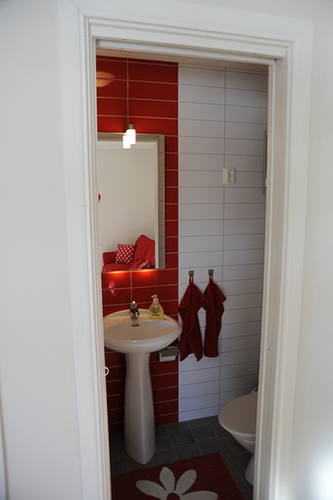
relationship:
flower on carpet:
[135, 465, 218, 500] [111, 448, 249, 500]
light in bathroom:
[121, 123, 137, 154] [93, 46, 264, 496]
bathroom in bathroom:
[0, 0, 333, 499] [93, 46, 264, 496]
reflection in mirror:
[103, 209, 163, 270] [98, 135, 160, 272]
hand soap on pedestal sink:
[148, 295, 164, 322] [103, 305, 183, 465]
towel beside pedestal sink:
[178, 271, 205, 362] [103, 305, 183, 465]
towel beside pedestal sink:
[203, 268, 225, 356] [103, 305, 183, 465]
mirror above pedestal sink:
[77, 113, 202, 305] [103, 305, 183, 465]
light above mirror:
[121, 123, 137, 150] [98, 136, 166, 269]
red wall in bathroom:
[98, 56, 179, 383] [93, 46, 264, 496]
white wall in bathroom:
[187, 63, 265, 424] [72, 43, 273, 499]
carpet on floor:
[111, 448, 249, 500] [109, 412, 253, 497]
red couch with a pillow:
[103, 234, 156, 271] [115, 243, 134, 264]